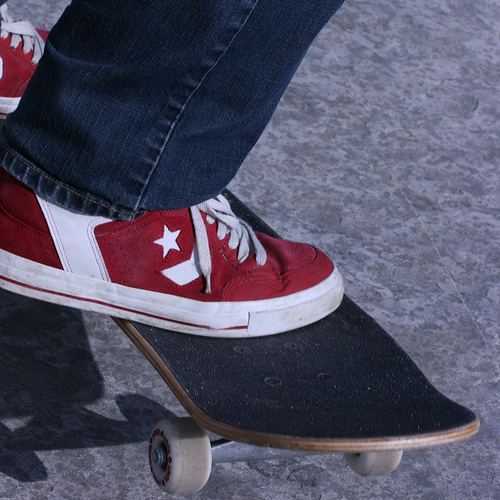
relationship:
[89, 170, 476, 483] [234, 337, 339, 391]
skateboard has bolts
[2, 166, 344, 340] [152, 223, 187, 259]
tennis shoe has a star design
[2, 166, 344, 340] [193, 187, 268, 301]
tennis shoe has laces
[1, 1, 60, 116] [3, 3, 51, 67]
tennis shoe has laces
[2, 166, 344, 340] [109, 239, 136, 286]
shoe has air holes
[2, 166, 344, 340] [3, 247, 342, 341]
shoe has rubber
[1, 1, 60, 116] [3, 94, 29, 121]
shoe has rubber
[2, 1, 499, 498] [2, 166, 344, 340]
picture has a shoe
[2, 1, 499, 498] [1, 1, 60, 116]
picture has a shoe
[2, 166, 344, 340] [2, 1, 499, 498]
shoe in picture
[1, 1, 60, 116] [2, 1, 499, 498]
shoe in picture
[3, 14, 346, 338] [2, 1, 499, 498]
shoes in picture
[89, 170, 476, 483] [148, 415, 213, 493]
skate board has a wheels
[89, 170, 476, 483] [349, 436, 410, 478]
skate board has a wheel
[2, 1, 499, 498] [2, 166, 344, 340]
picture has shoe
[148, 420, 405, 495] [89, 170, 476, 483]
wheels on board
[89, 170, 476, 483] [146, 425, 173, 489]
board has design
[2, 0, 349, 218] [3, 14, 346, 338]
legs have pants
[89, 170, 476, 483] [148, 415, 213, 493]
skate board has wheels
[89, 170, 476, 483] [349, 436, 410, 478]
skate board has wheel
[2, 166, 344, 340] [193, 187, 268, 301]
sneaker has laces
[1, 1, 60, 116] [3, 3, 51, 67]
sneaker has laces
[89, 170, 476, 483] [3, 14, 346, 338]
skateboard has feet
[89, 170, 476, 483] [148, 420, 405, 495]
skateboard has wheels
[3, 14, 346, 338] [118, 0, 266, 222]
pants have seam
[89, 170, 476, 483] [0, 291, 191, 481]
skateboard has shadow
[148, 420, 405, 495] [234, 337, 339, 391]
wheels have four bolts